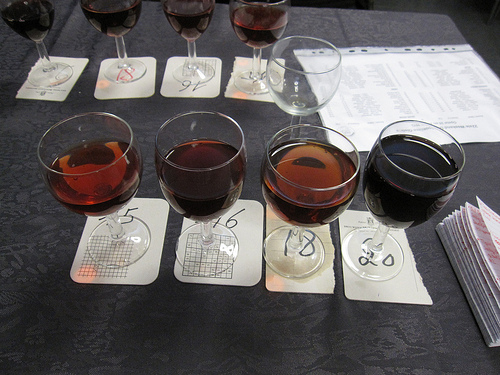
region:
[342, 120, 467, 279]
a glass of dark red wine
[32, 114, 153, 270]
a glass of light red wine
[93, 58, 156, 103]
a white coaster beneath a glass of wine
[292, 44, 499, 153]
a sheet of paper in a transparent folder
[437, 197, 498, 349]
a notebook on a table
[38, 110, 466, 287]
a row of glasses of wine on white coasters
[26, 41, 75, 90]
foot of a glass of wine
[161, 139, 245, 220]
red wine in a glass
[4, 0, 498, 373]
a black table with eight glasses of wine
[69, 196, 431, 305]
four white coasters on a black table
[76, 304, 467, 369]
The color of the table is black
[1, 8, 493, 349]
Several glasses on the table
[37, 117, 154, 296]
The glass of wine is the color dark red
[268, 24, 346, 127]
An empty glass on the table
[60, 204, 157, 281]
Glass number "15" on the table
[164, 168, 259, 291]
Glass number "16" on the table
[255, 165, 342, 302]
Glass number "18" on the table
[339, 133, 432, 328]
Glass number "20" on the table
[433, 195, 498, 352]
A notepad sitting on the table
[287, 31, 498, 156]
A piece of paper laid on the table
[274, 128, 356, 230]
liquid in a glass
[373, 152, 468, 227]
dark liquid in glass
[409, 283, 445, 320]
corner of a white napkin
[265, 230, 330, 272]
the number 18 under glass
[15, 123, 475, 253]
four different wine glasses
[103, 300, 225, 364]
table under wine glasses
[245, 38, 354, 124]
empty wine glass on table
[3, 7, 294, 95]
four wine glasses in background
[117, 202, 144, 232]
the number 5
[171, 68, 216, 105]
upside down number 16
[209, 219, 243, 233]
a number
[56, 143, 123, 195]
liquid in a glass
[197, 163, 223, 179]
rim of the glass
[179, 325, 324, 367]
a black table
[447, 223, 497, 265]
papers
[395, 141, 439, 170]
the liquid is black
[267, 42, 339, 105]
a clear wine glass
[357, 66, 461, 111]
paper on the table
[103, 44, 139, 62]
handle on the glass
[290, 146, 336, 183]
liquid is brown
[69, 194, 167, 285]
Place holder with number '5'.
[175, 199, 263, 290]
Place holder with number '16'.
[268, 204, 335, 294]
Place holder for wine tasting.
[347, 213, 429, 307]
Place holder is torn paper.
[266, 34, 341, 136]
Empty wine glass in center of table.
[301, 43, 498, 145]
Plastic protected paper on table.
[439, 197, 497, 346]
Notebook with lots of notes in red.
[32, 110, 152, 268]
Glass full half full of wine.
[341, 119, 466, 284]
Glass full of dark red wine.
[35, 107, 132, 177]
Rim of wine glass.